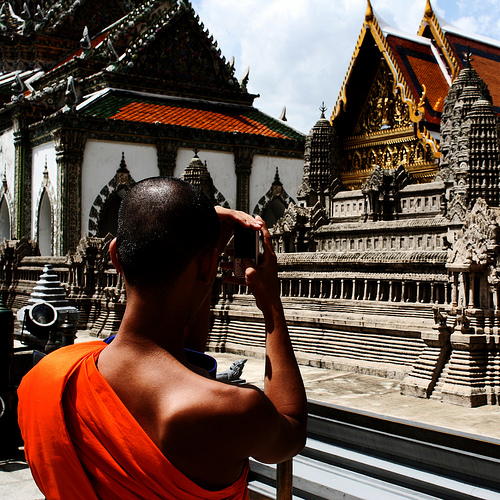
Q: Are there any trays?
A: No, there are no trays.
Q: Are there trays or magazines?
A: No, there are no trays or magazines.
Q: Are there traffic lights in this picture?
A: No, there are no traffic lights.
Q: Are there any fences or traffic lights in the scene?
A: No, there are no traffic lights or fences.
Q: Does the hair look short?
A: Yes, the hair is short.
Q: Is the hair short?
A: Yes, the hair is short.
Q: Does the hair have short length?
A: Yes, the hair is short.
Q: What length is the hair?
A: The hair is short.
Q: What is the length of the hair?
A: The hair is short.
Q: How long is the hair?
A: The hair is short.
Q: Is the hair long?
A: No, the hair is short.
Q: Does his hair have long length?
A: No, the hair is short.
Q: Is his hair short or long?
A: The hair is short.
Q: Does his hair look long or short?
A: The hair is short.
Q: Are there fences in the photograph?
A: No, there are no fences.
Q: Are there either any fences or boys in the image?
A: No, there are no fences or boys.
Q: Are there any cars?
A: No, there are no cars.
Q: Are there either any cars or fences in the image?
A: No, there are no cars or fences.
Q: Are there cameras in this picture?
A: Yes, there is a camera.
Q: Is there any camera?
A: Yes, there is a camera.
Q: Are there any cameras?
A: Yes, there is a camera.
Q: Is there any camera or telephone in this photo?
A: Yes, there is a camera.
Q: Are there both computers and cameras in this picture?
A: No, there is a camera but no computers.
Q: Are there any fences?
A: No, there are no fences.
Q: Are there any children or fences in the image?
A: No, there are no fences or children.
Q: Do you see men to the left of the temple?
A: Yes, there is a man to the left of the temple.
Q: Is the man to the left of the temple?
A: Yes, the man is to the left of the temple.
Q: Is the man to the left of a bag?
A: No, the man is to the left of the temple.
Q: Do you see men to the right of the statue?
A: No, the man is to the left of the statue.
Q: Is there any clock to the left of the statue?
A: No, there is a man to the left of the statue.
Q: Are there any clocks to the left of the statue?
A: No, there is a man to the left of the statue.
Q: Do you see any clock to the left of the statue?
A: No, there is a man to the left of the statue.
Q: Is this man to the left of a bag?
A: No, the man is to the left of the statue.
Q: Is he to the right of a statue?
A: No, the man is to the left of a statue.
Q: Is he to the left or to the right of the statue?
A: The man is to the left of the statue.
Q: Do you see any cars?
A: No, there are no cars.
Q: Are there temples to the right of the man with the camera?
A: Yes, there is a temple to the right of the man.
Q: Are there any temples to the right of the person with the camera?
A: Yes, there is a temple to the right of the man.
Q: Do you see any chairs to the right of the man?
A: No, there is a temple to the right of the man.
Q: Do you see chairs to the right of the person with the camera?
A: No, there is a temple to the right of the man.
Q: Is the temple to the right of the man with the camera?
A: Yes, the temple is to the right of the man.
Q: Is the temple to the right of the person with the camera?
A: Yes, the temple is to the right of the man.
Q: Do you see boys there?
A: No, there are no boys.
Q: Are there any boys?
A: No, there are no boys.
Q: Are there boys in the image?
A: No, there are no boys.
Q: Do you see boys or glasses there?
A: No, there are no boys or glasses.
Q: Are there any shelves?
A: No, there are no shelves.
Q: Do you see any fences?
A: No, there are no fences.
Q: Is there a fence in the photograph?
A: No, there are no fences.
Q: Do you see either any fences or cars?
A: No, there are no fences or cars.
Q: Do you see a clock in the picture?
A: No, there are no clocks.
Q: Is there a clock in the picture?
A: No, there are no clocks.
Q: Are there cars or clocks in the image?
A: No, there are no clocks or cars.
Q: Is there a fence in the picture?
A: No, there are no fences.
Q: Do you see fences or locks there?
A: No, there are no fences or locks.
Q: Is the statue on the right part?
A: Yes, the statue is on the right of the image.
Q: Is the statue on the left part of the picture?
A: No, the statue is on the right of the image.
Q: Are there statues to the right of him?
A: Yes, there is a statue to the right of the man.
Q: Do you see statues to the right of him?
A: Yes, there is a statue to the right of the man.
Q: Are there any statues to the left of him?
A: No, the statue is to the right of the man.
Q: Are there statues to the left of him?
A: No, the statue is to the right of the man.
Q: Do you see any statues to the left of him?
A: No, the statue is to the right of the man.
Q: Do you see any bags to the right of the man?
A: No, there is a statue to the right of the man.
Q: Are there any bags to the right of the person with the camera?
A: No, there is a statue to the right of the man.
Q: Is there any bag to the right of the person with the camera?
A: No, there is a statue to the right of the man.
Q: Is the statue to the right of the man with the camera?
A: Yes, the statue is to the right of the man.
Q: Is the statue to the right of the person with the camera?
A: Yes, the statue is to the right of the man.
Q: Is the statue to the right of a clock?
A: No, the statue is to the right of the man.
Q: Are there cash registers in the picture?
A: No, there are no cash registers.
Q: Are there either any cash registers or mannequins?
A: No, there are no cash registers or mannequins.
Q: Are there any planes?
A: No, there are no planes.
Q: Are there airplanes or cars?
A: No, there are no airplanes or cars.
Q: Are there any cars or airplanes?
A: No, there are no airplanes or cars.